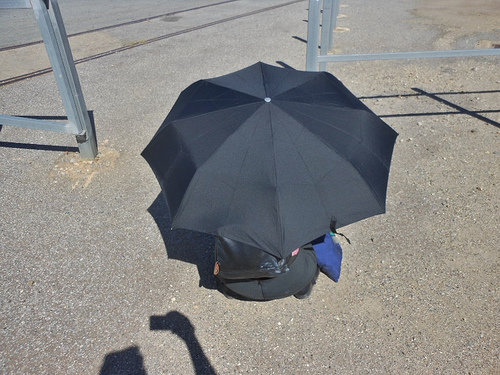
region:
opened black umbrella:
[144, 49, 401, 246]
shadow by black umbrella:
[75, 306, 249, 369]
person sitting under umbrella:
[217, 211, 380, 299]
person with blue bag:
[209, 222, 373, 296]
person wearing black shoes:
[278, 260, 349, 305]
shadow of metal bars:
[385, 69, 497, 134]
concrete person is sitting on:
[67, 204, 179, 311]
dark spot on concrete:
[157, 13, 190, 28]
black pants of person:
[227, 267, 342, 305]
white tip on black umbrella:
[259, 90, 280, 115]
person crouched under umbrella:
[32, 30, 447, 350]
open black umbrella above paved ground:
[141, 45, 411, 255]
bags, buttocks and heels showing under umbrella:
[200, 236, 355, 306]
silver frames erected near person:
[10, 5, 490, 165]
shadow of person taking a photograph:
[75, 285, 220, 370]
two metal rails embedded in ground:
[5, 0, 295, 90]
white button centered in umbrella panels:
[260, 85, 276, 110]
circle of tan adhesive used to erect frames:
[45, 120, 120, 190]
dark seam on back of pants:
[215, 261, 311, 301]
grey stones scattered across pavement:
[385, 5, 475, 166]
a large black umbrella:
[142, 57, 397, 252]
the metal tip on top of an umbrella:
[260, 94, 273, 104]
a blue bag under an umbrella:
[315, 236, 342, 278]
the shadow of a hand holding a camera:
[145, 309, 219, 374]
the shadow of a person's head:
[94, 345, 136, 373]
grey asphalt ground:
[16, 210, 125, 307]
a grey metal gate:
[21, 23, 92, 163]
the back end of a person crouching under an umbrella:
[200, 223, 324, 317]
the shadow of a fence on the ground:
[381, 83, 498, 122]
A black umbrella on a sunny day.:
[123, 42, 406, 262]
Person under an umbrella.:
[140, 25, 395, 332]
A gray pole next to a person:
[26, 5, 112, 182]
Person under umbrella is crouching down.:
[181, 217, 377, 313]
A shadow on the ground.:
[33, 288, 241, 371]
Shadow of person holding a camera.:
[135, 293, 200, 338]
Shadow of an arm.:
[135, 303, 250, 373]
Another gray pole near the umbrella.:
[297, 0, 329, 70]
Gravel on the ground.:
[20, 213, 135, 288]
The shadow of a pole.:
[410, 76, 497, 131]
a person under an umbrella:
[149, 55, 400, 318]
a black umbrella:
[136, 54, 413, 246]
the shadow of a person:
[101, 300, 214, 368]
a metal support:
[46, 5, 87, 162]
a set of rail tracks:
[120, 20, 157, 49]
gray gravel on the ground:
[370, 262, 427, 324]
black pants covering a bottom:
[234, 273, 308, 297]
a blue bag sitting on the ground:
[306, 235, 349, 277]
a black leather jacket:
[220, 245, 271, 280]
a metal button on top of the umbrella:
[249, 89, 291, 116]